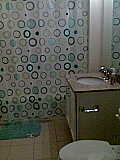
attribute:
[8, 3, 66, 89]
wall — white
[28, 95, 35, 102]
circle — red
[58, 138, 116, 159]
lid — white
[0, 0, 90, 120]
curtain — multi colored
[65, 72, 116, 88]
counter — brown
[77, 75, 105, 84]
sink — white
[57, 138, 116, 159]
toilet — white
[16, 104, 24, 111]
circle — green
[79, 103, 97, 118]
holder — empty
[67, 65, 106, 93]
sink — white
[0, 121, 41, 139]
mat — blue green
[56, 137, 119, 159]
porcelain — white